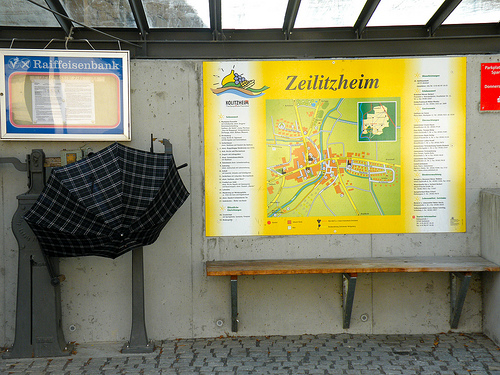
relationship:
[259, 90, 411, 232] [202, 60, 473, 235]
map on map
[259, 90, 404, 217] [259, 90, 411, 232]
map on map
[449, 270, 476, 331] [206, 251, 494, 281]
bar under bench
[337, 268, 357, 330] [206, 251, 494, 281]
bar under bench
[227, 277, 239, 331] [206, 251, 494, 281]
bar under bench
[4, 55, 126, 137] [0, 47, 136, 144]
poster by glass case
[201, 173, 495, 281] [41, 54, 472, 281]
bench on wall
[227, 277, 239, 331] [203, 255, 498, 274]
bar on bench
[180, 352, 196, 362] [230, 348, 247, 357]
cobblestone on bricks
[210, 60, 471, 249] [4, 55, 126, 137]
map on poster